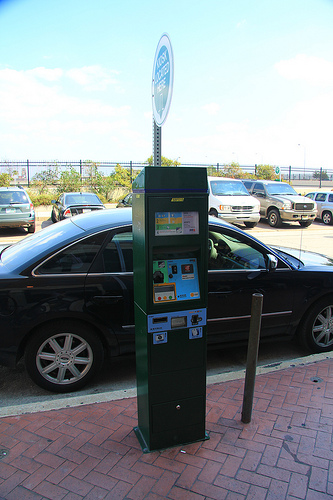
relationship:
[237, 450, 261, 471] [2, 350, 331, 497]
bricks on sidewalk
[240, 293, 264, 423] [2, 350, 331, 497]
pole in sidewalk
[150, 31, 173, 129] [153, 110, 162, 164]
street sign on street pole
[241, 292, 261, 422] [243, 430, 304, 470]
pole on ground